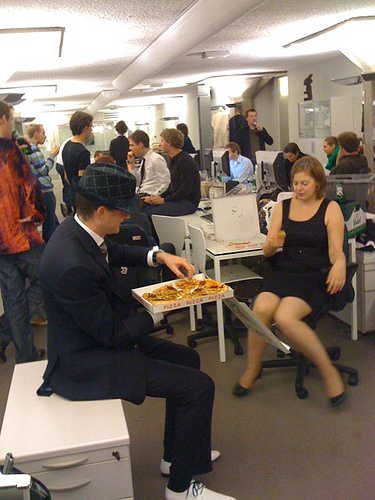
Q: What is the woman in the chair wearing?
A: A dress.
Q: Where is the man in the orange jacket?
A: Behind the man in the hat.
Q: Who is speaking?
A: The man with the microphone.